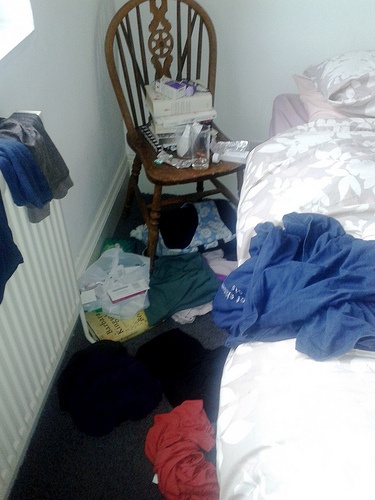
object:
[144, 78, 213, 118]
book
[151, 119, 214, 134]
book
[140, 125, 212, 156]
book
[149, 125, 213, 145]
book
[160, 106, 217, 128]
books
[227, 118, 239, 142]
ground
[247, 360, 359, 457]
light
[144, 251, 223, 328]
clothing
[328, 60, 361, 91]
pattern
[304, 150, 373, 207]
pattern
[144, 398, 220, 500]
clothes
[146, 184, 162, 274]
leg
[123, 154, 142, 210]
leg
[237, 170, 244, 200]
leg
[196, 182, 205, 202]
leg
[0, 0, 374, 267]
wall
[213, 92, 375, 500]
bed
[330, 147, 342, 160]
leaf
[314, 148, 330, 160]
leaf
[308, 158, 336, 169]
leaf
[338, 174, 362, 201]
leaf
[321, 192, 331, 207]
leaf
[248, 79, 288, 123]
ground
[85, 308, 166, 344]
book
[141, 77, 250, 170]
stacked stuff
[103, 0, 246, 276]
brown chair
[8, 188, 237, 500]
floor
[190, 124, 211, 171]
glass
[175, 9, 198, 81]
spindle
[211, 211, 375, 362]
clothes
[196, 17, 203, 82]
spindle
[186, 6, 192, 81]
spindle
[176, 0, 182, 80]
spindle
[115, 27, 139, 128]
spindle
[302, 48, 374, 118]
pillow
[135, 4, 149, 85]
spindle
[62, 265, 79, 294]
part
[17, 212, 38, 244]
part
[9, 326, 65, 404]
part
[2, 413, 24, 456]
part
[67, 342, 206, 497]
dark color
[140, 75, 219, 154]
stack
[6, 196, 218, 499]
carpet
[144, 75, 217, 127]
cover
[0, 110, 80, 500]
heater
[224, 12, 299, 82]
area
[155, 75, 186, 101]
box